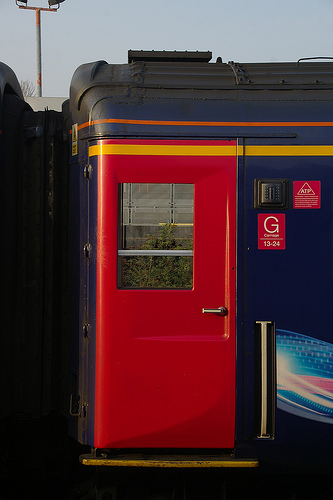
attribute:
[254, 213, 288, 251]
sign — red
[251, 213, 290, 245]
g — white, big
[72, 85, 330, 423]
train — train car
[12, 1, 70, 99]
pole — red, tall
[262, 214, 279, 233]
g — big, white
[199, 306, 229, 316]
lever — metal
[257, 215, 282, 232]
big g — white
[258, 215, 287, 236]
white g — big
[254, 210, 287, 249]
car — identification label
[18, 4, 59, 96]
pole — orange, white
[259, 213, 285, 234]
letter — G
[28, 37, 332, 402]
train — dark blue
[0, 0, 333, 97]
sky — grey, hazy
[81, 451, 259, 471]
platform — small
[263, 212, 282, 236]
g — white, big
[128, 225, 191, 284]
tree reflection — evergreen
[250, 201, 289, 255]
sign — white, red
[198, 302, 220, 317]
handle — silver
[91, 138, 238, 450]
door — red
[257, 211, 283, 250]
letters — white